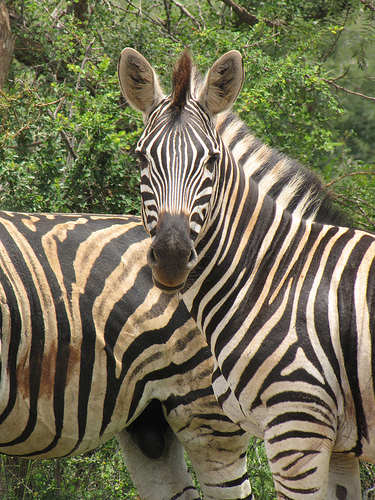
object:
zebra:
[0, 210, 257, 500]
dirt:
[11, 337, 84, 401]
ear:
[116, 46, 164, 116]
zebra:
[117, 44, 375, 500]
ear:
[198, 48, 246, 115]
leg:
[163, 409, 260, 500]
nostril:
[186, 246, 198, 269]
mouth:
[150, 274, 186, 296]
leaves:
[35, 134, 59, 172]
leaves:
[2, 112, 17, 137]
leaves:
[281, 115, 301, 138]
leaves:
[322, 21, 346, 39]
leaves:
[0, 94, 19, 115]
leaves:
[33, 103, 52, 127]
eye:
[136, 148, 150, 171]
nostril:
[147, 245, 157, 265]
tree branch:
[223, 0, 256, 26]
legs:
[262, 405, 365, 500]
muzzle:
[145, 228, 197, 296]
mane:
[215, 111, 351, 227]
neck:
[180, 128, 284, 354]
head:
[116, 44, 245, 297]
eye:
[205, 151, 221, 167]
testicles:
[126, 398, 168, 462]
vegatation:
[0, 0, 375, 228]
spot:
[5, 262, 56, 338]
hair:
[171, 47, 194, 109]